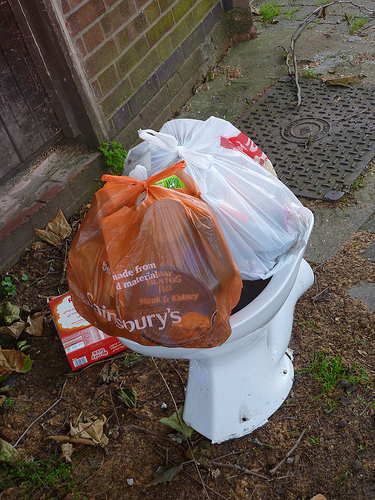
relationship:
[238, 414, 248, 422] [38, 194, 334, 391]
screw on toilet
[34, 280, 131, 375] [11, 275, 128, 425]
box on ground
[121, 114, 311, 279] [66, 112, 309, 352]
bag has garbage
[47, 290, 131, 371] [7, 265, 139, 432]
box on ground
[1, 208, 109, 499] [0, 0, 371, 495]
leaves on ground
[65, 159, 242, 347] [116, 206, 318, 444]
bag on porcelain toilet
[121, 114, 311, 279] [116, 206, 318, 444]
bag on porcelain toilet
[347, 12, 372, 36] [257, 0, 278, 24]
clump of clump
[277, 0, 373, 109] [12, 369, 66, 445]
twig on twig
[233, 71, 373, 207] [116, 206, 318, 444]
grate behind porcelain toilet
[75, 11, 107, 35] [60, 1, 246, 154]
line between bricks